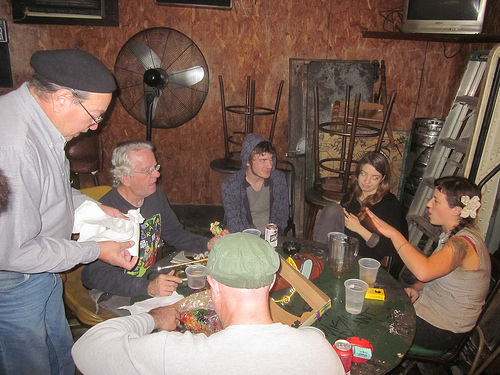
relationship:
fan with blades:
[109, 24, 214, 140] [131, 33, 203, 88]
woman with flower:
[410, 171, 496, 361] [455, 192, 485, 221]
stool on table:
[218, 66, 284, 170] [210, 155, 241, 178]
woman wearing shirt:
[323, 148, 407, 282] [340, 183, 403, 252]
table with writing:
[131, 214, 380, 373] [321, 311, 382, 334]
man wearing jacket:
[213, 124, 297, 241] [215, 126, 298, 232]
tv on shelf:
[396, 1, 493, 41] [350, 24, 484, 52]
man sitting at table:
[0, 47, 145, 373] [84, 229, 416, 374]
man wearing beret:
[3, 34, 145, 373] [32, 45, 112, 107]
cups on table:
[344, 277, 369, 316] [135, 230, 420, 367]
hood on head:
[235, 130, 272, 167] [232, 125, 282, 188]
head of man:
[232, 125, 282, 188] [213, 130, 294, 235]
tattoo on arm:
[448, 240, 470, 273] [359, 204, 479, 283]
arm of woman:
[359, 204, 479, 283] [374, 167, 483, 373]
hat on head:
[180, 237, 277, 292] [425, 140, 482, 230]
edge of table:
[385, 294, 424, 355] [135, 230, 420, 367]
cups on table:
[323, 227, 383, 316] [127, 236, 419, 373]